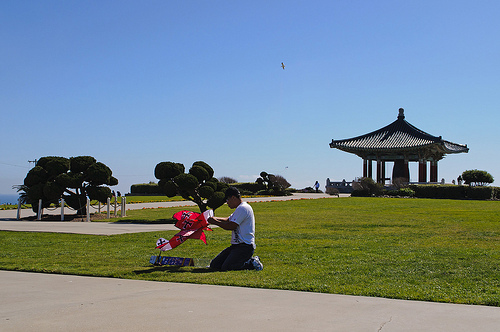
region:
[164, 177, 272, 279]
Man with a red and black kite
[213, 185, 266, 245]
Man is wearing a white tshirt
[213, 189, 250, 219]
Man wearing black baseball cap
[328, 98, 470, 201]
A Chinese pagoda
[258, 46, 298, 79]
A kite in the sky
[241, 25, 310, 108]
Kite in the sky on a summer day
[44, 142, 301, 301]
Man in a park to fly a kite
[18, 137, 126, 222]
Ornamental bushes in a park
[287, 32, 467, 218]
A pagoda on the hill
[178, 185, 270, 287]
Man kneeling on grass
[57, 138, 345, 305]
a man kneeling in the grass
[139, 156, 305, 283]
a man holding an airplane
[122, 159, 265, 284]
a man holding a plane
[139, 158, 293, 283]
a man kneeling on the grass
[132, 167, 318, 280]
a man holding a kite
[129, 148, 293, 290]
a man holding an airplane kite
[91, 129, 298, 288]
a man holding a plane kite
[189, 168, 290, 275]
a man waring a hat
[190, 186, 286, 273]
a man wearing a shirt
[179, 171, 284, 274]
a man wearing jeans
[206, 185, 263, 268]
man holding a kite while kneeling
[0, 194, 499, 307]
a grassy area in front of the pagoda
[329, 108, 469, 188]
a pagoda behind the man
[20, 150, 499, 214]
small plants around the grassy area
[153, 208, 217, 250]
a red and white kite in the man's hands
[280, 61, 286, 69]
a small kite in the air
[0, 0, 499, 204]
clear blue sky behind the pagoda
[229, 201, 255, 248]
a white t-shirt on the man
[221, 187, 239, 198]
a hat on the man's head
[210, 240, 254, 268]
blue jeans on the man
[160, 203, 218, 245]
black and red kite hled by man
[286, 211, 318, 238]
short green and brown grass at park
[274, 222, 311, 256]
short green and brown grass at park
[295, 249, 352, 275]
short green and brown grass at park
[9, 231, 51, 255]
short green and brown grass at park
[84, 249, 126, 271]
short green and brown grass at park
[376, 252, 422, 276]
short green and brown grass at park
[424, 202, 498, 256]
short green and brown grass at park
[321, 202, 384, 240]
short green and brown grass at park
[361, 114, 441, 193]
gray temple like structure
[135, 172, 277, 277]
A man is flying his toy airplane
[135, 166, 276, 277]
A man is checking a model airplane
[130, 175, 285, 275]
A man is kneeling on the grass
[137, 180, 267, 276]
A man fixing his airplane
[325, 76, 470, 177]
An oriental style covered pavilion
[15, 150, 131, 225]
A tree is in a park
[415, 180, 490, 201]
Bushes are in a park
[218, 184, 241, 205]
A man is wearing a hat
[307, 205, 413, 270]
Grass inside of a park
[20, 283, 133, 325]
A sidewalk beside a park